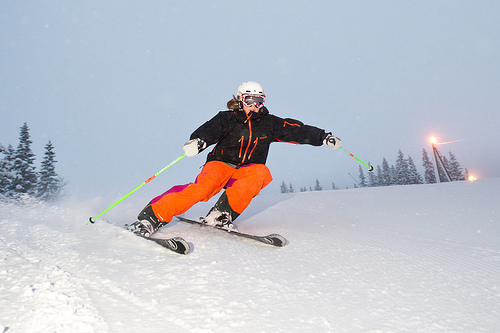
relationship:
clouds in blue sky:
[0, 0, 500, 182] [3, 3, 499, 200]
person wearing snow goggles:
[124, 79, 344, 237] [237, 90, 270, 111]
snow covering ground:
[1, 171, 484, 331] [1, 173, 484, 331]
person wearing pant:
[124, 79, 344, 237] [136, 161, 273, 229]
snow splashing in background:
[1, 171, 500, 333] [2, 119, 482, 234]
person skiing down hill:
[124, 79, 344, 237] [2, 183, 484, 330]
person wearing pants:
[124, 79, 344, 237] [136, 159, 273, 231]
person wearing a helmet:
[124, 79, 344, 237] [232, 74, 279, 108]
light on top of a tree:
[423, 128, 444, 155] [421, 126, 458, 196]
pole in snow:
[83, 148, 193, 226] [83, 213, 318, 330]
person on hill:
[124, 79, 344, 237] [132, 167, 414, 330]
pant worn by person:
[216, 55, 275, 135] [124, 79, 344, 237]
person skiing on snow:
[124, 79, 344, 237] [1, 171, 484, 331]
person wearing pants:
[127, 76, 348, 244] [136, 159, 273, 231]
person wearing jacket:
[124, 79, 344, 237] [184, 110, 333, 169]